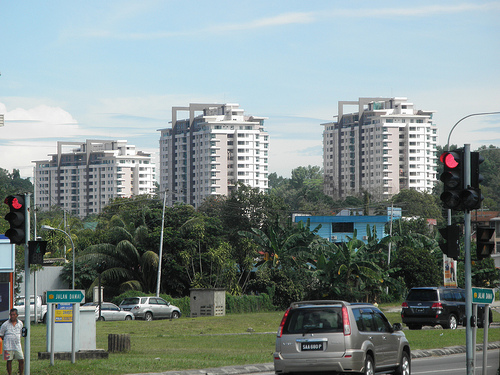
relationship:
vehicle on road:
[265, 290, 417, 375] [409, 335, 498, 374]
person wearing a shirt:
[3, 306, 37, 375] [1, 319, 30, 350]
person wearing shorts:
[3, 306, 37, 375] [3, 351, 31, 365]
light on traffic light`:
[1, 193, 27, 209] [6, 189, 32, 249]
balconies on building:
[157, 130, 277, 163] [154, 97, 272, 201]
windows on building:
[229, 135, 257, 188] [154, 97, 272, 201]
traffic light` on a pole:
[6, 189, 32, 249] [20, 188, 34, 375]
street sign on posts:
[39, 288, 88, 307] [45, 304, 89, 366]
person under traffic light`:
[3, 306, 37, 375] [6, 189, 32, 249]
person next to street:
[3, 306, 37, 375] [4, 360, 282, 374]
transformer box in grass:
[185, 282, 230, 318] [141, 333, 250, 373]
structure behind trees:
[289, 208, 410, 249] [77, 198, 462, 301]